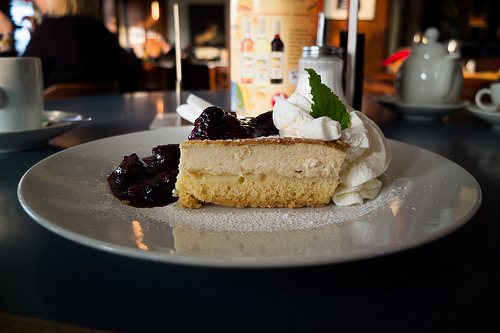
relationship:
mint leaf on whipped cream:
[305, 64, 352, 132] [277, 84, 391, 205]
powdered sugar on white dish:
[58, 153, 459, 214] [17, 123, 484, 270]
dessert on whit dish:
[110, 66, 393, 210] [17, 123, 484, 270]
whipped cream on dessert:
[277, 84, 391, 205] [110, 66, 393, 210]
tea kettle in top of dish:
[390, 27, 467, 114] [373, 95, 468, 122]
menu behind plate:
[219, 1, 324, 122] [17, 123, 484, 270]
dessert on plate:
[110, 66, 393, 210] [17, 123, 484, 270]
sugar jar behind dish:
[298, 43, 348, 107] [17, 123, 484, 270]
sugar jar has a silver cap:
[298, 43, 348, 107] [300, 44, 345, 59]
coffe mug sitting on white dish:
[0, 55, 47, 133] [0, 110, 86, 156]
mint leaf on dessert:
[305, 64, 352, 132] [110, 66, 393, 210]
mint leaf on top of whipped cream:
[305, 64, 352, 132] [277, 84, 391, 205]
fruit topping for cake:
[111, 109, 284, 209] [178, 124, 351, 213]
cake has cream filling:
[178, 124, 351, 213] [182, 158, 341, 181]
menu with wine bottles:
[219, 1, 324, 122] [239, 20, 288, 97]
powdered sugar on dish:
[58, 153, 459, 214] [17, 123, 484, 270]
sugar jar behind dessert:
[298, 43, 348, 107] [110, 66, 393, 210]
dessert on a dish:
[110, 66, 393, 210] [17, 123, 484, 270]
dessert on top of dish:
[110, 66, 393, 210] [17, 123, 484, 270]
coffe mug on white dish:
[0, 55, 47, 133] [0, 110, 86, 156]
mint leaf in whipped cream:
[305, 64, 352, 132] [277, 84, 391, 205]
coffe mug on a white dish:
[0, 55, 47, 133] [0, 110, 86, 156]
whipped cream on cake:
[277, 84, 391, 205] [178, 124, 351, 213]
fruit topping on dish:
[111, 109, 284, 209] [17, 123, 484, 270]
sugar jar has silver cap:
[298, 43, 348, 107] [300, 44, 345, 59]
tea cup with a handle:
[474, 81, 498, 113] [474, 87, 496, 114]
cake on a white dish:
[178, 124, 351, 213] [17, 123, 484, 270]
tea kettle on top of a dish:
[390, 27, 467, 114] [373, 95, 468, 122]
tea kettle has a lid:
[390, 27, 467, 114] [412, 29, 450, 58]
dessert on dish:
[110, 66, 393, 210] [17, 123, 484, 270]